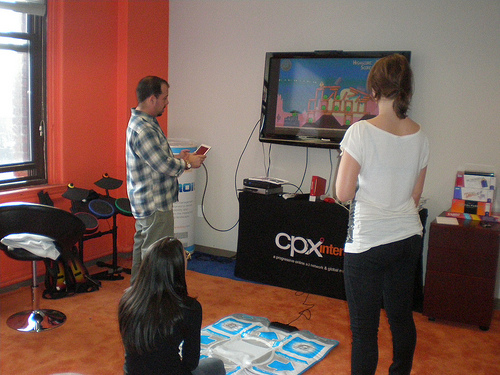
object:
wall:
[0, 0, 169, 291]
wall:
[168, 0, 497, 263]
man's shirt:
[122, 106, 192, 221]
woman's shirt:
[337, 116, 433, 255]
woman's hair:
[363, 49, 418, 119]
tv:
[260, 46, 415, 148]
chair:
[1, 201, 84, 336]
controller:
[186, 143, 212, 172]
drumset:
[60, 172, 133, 282]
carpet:
[0, 251, 500, 375]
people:
[331, 48, 434, 375]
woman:
[115, 232, 227, 375]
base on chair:
[5, 261, 68, 335]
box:
[448, 162, 498, 217]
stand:
[421, 209, 500, 332]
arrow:
[265, 358, 297, 372]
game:
[178, 311, 341, 374]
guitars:
[35, 188, 103, 301]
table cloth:
[232, 188, 431, 313]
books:
[469, 213, 482, 227]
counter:
[429, 207, 500, 233]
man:
[123, 74, 209, 301]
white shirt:
[0, 232, 61, 262]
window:
[0, 0, 49, 190]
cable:
[199, 118, 261, 234]